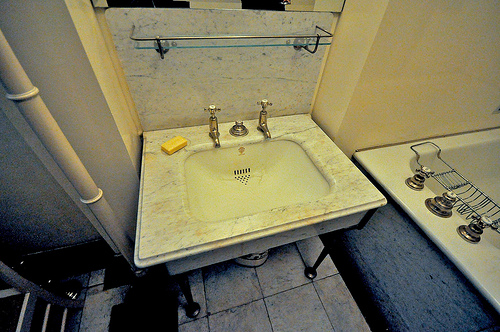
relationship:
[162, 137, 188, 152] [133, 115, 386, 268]
soap on sink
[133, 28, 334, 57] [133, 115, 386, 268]
shelf above sink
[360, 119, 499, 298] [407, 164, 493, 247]
tub has faucets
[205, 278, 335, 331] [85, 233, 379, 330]
tile on floor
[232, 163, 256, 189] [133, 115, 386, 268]
drain in sink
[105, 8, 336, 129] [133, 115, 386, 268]
backsplash above sink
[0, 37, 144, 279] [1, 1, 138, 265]
pipe near wall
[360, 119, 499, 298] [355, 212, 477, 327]
tub has marble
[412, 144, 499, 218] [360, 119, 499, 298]
rack in tub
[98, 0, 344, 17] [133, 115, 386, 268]
mirror above sink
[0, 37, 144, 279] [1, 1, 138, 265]
pipe going up wall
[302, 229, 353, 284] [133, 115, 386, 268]
leg of sink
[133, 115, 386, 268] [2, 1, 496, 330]
sink in bathroom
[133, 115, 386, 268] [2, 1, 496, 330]
sink in a bathroom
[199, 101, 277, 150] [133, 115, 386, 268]
faucets on sink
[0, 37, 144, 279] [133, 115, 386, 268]
pipe next to sink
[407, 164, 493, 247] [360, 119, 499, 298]
faucets on tub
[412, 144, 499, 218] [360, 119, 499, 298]
rack on tub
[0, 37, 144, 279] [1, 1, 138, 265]
pipe along wall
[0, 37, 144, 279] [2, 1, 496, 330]
pipe in bathroom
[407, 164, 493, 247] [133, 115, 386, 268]
faucets on sink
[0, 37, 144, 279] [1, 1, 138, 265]
pipe against wall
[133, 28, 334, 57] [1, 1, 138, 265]
shelf on wall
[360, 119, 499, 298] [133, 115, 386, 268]
tub next to sink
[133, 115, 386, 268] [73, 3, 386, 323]
sink against wall